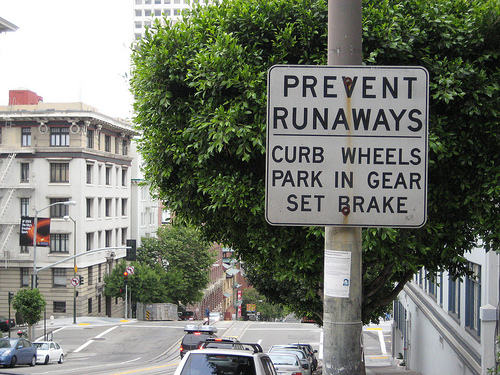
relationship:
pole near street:
[320, 1, 364, 375] [0, 311, 393, 374]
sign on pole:
[264, 62, 430, 229] [320, 1, 364, 375]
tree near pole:
[129, 0, 499, 374] [320, 1, 364, 375]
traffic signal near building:
[123, 269, 129, 286] [0, 89, 145, 319]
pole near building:
[128, 282, 133, 319] [0, 89, 145, 319]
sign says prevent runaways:
[264, 62, 430, 229] [272, 74, 423, 133]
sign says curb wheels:
[264, 62, 430, 229] [272, 145, 422, 165]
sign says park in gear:
[264, 62, 430, 229] [272, 169, 422, 190]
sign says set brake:
[264, 62, 430, 229] [286, 194, 409, 215]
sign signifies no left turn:
[125, 264, 136, 278] [127, 266, 133, 274]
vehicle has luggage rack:
[173, 338, 280, 374] [202, 339, 264, 354]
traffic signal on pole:
[123, 269, 129, 286] [125, 285, 129, 323]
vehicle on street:
[0, 337, 38, 369] [0, 311, 393, 374]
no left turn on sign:
[71, 279, 78, 286] [71, 275, 80, 289]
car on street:
[32, 339, 68, 367] [0, 311, 393, 374]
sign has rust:
[264, 62, 430, 229] [343, 76, 356, 135]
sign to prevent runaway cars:
[264, 62, 430, 229] [272, 74, 423, 133]